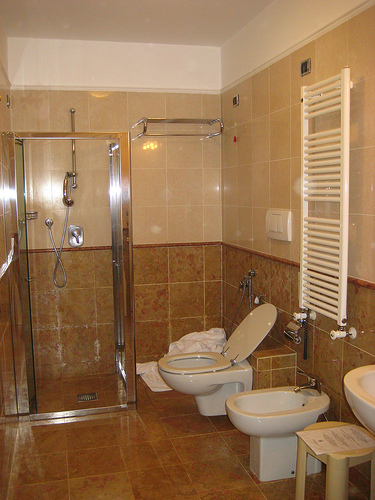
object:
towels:
[136, 326, 227, 391]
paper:
[293, 420, 374, 456]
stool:
[293, 421, 375, 500]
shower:
[12, 129, 137, 415]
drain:
[76, 392, 98, 403]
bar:
[136, 115, 224, 140]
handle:
[67, 224, 85, 249]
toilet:
[154, 303, 278, 418]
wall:
[5, 29, 226, 383]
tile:
[0, 8, 375, 284]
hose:
[43, 107, 77, 287]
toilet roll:
[283, 311, 308, 345]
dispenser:
[283, 311, 317, 360]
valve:
[68, 224, 84, 247]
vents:
[290, 65, 358, 342]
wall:
[219, 0, 375, 427]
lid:
[222, 303, 277, 366]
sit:
[155, 350, 232, 376]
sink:
[224, 385, 329, 483]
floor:
[13, 366, 375, 500]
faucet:
[293, 368, 321, 395]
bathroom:
[0, 0, 375, 500]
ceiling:
[0, 0, 375, 94]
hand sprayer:
[62, 170, 77, 206]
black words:
[311, 427, 368, 451]